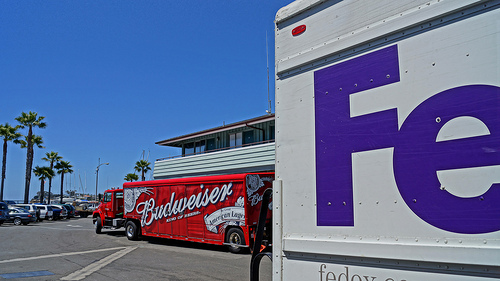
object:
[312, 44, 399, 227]
f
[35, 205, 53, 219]
car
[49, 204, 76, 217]
car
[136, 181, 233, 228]
letters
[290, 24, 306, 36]
reflector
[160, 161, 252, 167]
wall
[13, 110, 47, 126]
palms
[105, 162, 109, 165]
light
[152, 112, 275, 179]
hotel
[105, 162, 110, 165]
light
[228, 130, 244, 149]
window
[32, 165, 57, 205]
palm tree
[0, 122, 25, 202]
palm tree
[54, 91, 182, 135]
blue sky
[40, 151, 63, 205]
palm tree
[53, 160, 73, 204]
palm tree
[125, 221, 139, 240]
tire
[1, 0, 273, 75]
sky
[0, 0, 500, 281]
photo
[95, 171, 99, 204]
pole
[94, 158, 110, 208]
street light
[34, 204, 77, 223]
parking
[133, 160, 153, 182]
pines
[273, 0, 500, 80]
part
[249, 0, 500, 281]
truck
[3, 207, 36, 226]
car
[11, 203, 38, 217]
car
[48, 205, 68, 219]
car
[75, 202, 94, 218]
car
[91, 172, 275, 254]
beer truck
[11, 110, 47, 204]
palm tree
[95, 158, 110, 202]
light pole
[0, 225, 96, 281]
road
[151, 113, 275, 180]
building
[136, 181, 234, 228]
budweiser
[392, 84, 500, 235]
letter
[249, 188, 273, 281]
door handle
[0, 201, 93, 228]
parking lot